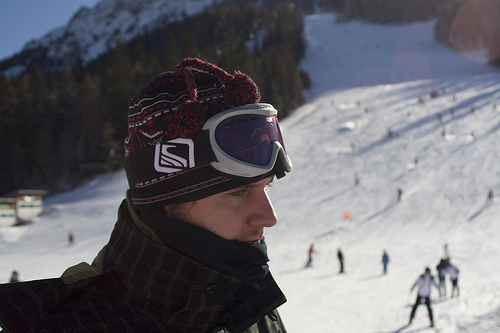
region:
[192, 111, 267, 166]
the goggles are on the hat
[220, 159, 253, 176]
the goggles are silver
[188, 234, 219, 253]
the coat is black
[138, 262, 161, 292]
the coat has lines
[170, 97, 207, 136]
the hat has fur ball on it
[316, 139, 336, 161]
the hill has snow on it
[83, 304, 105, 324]
the coat is brown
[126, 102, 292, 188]
Grey goggles with a black and white band.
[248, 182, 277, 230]
Nose on a man's face.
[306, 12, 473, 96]
Ski slope coming down a hill further up.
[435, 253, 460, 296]
To people down the hill with their heads together for a photo.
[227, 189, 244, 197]
A man's right eye.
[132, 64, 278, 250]
The head of a man with goggles on his head.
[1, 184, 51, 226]
A building in the background with two large garage doors.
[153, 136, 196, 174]
White design on the man's black strap of his goggles.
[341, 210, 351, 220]
An orange cone down in the snow.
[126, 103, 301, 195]
goggles on the top of the face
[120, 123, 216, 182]
black and white strap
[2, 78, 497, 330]
people on the snow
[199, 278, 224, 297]
button on the fabric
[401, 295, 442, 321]
legs are wide apart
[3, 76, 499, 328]
ground is covered in white snow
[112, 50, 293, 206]
red, black, and red cap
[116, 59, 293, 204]
cap on the head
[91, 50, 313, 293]
a man's head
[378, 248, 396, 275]
skier on the slope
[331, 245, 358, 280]
skier on the slope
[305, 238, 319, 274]
skier on the slope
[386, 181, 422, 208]
skier on the slope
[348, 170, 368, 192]
skier on the slope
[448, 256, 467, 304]
skier on the slope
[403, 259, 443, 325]
skier on the slope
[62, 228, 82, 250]
skier on the slope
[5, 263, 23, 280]
skier on the slope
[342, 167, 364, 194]
skier on the slope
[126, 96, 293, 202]
goggles on man's head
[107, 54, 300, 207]
man wearing a hat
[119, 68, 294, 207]
hat is red and black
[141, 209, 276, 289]
scarf around man's face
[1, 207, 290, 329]
man wearing a jacket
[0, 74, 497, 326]
people skiing bheind man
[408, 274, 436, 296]
person wearing white jacket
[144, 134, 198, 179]
white logo on hat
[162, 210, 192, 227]
man has a beard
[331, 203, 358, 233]
orange object in snow